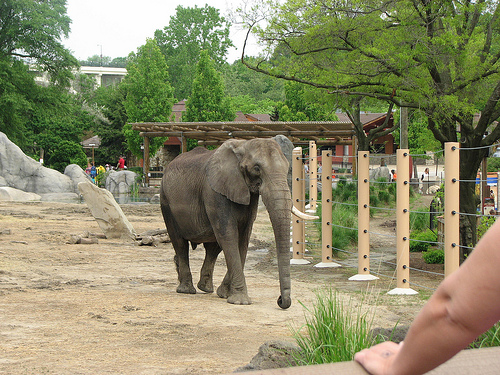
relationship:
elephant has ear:
[159, 134, 294, 308] [207, 138, 252, 206]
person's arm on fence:
[363, 249, 489, 363] [437, 338, 488, 368]